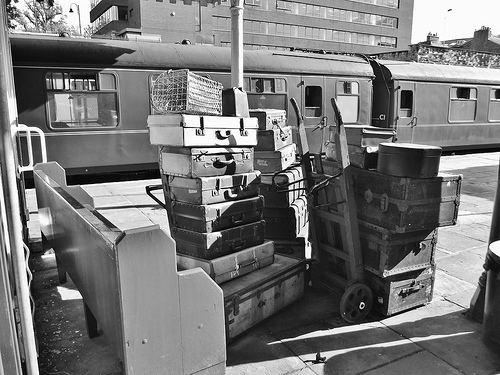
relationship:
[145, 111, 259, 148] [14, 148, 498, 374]
luggage piled on ground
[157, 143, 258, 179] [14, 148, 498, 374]
luggage piled on ground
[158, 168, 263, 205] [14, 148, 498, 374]
luggage piled on ground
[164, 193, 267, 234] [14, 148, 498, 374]
luggage piled on ground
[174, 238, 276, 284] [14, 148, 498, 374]
luggage piled on ground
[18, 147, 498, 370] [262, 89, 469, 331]
sidewalk behind cart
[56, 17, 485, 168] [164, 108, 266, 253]
train behind luggage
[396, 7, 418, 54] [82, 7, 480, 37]
wall on building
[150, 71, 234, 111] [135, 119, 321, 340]
cage on luggage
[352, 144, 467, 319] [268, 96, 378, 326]
chests on train carts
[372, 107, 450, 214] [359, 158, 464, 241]
box on chests